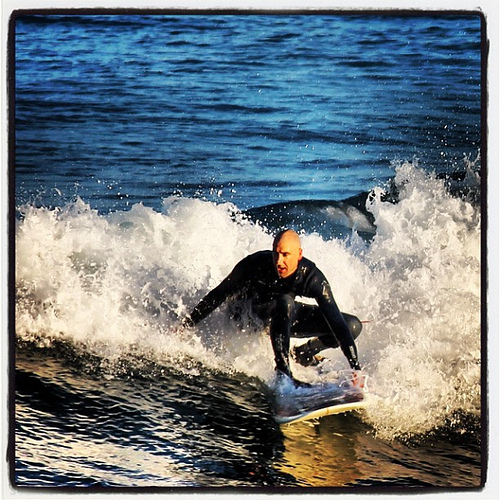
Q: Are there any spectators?
A: No, there are no spectators.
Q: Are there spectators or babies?
A: No, there are no spectators or babies.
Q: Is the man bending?
A: Yes, the man is bending.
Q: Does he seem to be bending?
A: Yes, the man is bending.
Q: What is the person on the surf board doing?
A: The man is bending.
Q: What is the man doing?
A: The man is bending.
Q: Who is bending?
A: The man is bending.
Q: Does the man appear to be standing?
A: No, the man is bending.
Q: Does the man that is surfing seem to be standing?
A: No, the man is bending.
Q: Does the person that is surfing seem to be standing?
A: No, the man is bending.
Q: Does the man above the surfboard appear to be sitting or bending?
A: The man is bending.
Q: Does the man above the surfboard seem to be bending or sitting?
A: The man is bending.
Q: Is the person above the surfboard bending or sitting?
A: The man is bending.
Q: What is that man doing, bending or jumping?
A: The man is bending.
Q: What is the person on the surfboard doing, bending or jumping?
A: The man is bending.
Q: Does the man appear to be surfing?
A: Yes, the man is surfing.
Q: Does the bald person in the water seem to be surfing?
A: Yes, the man is surfing.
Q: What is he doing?
A: The man is surfing.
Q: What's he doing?
A: The man is surfing.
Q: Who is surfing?
A: The man is surfing.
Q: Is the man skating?
A: No, the man is surfing.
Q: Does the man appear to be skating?
A: No, the man is surfing.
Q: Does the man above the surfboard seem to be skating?
A: No, the man is surfing.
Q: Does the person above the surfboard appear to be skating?
A: No, the man is surfing.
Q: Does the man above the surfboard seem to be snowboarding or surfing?
A: The man is surfing.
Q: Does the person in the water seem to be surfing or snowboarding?
A: The man is surfing.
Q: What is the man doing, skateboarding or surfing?
A: The man is surfing.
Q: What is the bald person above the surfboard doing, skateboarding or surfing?
A: The man is surfing.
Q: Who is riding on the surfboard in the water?
A: The man is riding on the surfboard.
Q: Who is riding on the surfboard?
A: The man is riding on the surfboard.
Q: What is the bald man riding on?
A: The man is riding on the surfboard.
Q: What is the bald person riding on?
A: The man is riding on the surfboard.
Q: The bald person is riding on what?
A: The man is riding on the surfboard.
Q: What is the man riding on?
A: The man is riding on the surfboard.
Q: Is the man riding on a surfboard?
A: Yes, the man is riding on a surfboard.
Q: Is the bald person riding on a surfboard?
A: Yes, the man is riding on a surfboard.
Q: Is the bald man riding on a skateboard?
A: No, the man is riding on a surfboard.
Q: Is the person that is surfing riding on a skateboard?
A: No, the man is riding on a surfboard.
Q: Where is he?
A: The man is in the water.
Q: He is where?
A: The man is in the water.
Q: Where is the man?
A: The man is in the water.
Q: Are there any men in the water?
A: Yes, there is a man in the water.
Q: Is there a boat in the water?
A: No, there is a man in the water.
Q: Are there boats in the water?
A: No, there is a man in the water.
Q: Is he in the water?
A: Yes, the man is in the water.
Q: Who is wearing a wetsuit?
A: The man is wearing a wetsuit.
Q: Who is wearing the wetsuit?
A: The man is wearing a wetsuit.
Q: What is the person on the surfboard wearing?
A: The man is wearing a wetsuit.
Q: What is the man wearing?
A: The man is wearing a wetsuit.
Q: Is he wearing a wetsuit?
A: Yes, the man is wearing a wetsuit.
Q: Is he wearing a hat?
A: No, the man is wearing a wetsuit.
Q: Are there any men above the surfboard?
A: Yes, there is a man above the surfboard.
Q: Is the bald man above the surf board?
A: Yes, the man is above the surf board.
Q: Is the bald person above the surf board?
A: Yes, the man is above the surf board.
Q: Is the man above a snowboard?
A: No, the man is above the surf board.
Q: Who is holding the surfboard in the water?
A: The man is holding the surfboard.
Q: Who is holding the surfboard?
A: The man is holding the surfboard.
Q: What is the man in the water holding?
A: The man is holding the surf board.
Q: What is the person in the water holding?
A: The man is holding the surf board.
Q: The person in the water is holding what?
A: The man is holding the surf board.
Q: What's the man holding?
A: The man is holding the surf board.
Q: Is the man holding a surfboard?
A: Yes, the man is holding a surfboard.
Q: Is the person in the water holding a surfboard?
A: Yes, the man is holding a surfboard.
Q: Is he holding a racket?
A: No, the man is holding a surfboard.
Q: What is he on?
A: The man is on the surfboard.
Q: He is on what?
A: The man is on the surfboard.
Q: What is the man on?
A: The man is on the surfboard.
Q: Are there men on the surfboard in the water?
A: Yes, there is a man on the surfboard.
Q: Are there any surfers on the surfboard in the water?
A: No, there is a man on the surfboard.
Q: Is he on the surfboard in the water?
A: Yes, the man is on the surfboard.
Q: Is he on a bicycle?
A: No, the man is on the surfboard.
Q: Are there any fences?
A: No, there are no fences.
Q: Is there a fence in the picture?
A: No, there are no fences.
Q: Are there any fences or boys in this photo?
A: No, there are no fences or boys.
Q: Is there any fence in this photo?
A: No, there are no fences.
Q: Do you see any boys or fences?
A: No, there are no fences or boys.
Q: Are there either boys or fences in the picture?
A: No, there are no fences or boys.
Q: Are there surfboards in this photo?
A: Yes, there is a surfboard.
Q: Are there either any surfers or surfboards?
A: Yes, there is a surfboard.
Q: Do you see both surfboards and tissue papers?
A: No, there is a surfboard but no tissues.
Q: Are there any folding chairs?
A: No, there are no folding chairs.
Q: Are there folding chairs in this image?
A: No, there are no folding chairs.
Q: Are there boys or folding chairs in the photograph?
A: No, there are no folding chairs or boys.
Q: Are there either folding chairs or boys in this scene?
A: No, there are no folding chairs or boys.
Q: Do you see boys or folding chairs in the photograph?
A: No, there are no folding chairs or boys.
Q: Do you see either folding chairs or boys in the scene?
A: No, there are no folding chairs or boys.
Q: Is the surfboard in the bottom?
A: Yes, the surfboard is in the bottom of the image.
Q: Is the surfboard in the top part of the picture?
A: No, the surfboard is in the bottom of the image.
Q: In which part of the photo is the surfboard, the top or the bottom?
A: The surfboard is in the bottom of the image.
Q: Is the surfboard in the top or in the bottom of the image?
A: The surfboard is in the bottom of the image.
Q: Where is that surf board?
A: The surf board is in the water.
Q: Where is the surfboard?
A: The surf board is in the water.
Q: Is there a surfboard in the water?
A: Yes, there is a surfboard in the water.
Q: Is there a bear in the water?
A: No, there is a surfboard in the water.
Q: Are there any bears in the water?
A: No, there is a surfboard in the water.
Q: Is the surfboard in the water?
A: Yes, the surfboard is in the water.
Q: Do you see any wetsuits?
A: Yes, there is a wetsuit.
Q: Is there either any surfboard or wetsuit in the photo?
A: Yes, there is a wetsuit.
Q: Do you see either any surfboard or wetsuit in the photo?
A: Yes, there is a wetsuit.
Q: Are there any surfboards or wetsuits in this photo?
A: Yes, there is a wetsuit.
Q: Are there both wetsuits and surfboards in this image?
A: Yes, there are both a wetsuit and a surfboard.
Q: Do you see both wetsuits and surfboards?
A: Yes, there are both a wetsuit and a surfboard.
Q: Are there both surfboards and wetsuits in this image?
A: Yes, there are both a wetsuit and a surfboard.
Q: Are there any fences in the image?
A: No, there are no fences.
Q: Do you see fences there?
A: No, there are no fences.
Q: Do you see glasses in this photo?
A: No, there are no glasses.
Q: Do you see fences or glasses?
A: No, there are no glasses or fences.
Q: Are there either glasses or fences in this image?
A: No, there are no glasses or fences.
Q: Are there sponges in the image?
A: No, there are no sponges.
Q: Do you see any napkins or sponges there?
A: No, there are no sponges or napkins.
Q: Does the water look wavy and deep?
A: Yes, the water is wavy and deep.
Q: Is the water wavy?
A: Yes, the water is wavy.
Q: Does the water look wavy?
A: Yes, the water is wavy.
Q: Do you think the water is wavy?
A: Yes, the water is wavy.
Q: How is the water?
A: The water is wavy.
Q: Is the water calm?
A: No, the water is wavy.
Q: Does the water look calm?
A: No, the water is wavy.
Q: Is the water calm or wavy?
A: The water is wavy.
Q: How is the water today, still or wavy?
A: The water is wavy.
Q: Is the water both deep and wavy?
A: Yes, the water is deep and wavy.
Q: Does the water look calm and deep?
A: No, the water is deep but wavy.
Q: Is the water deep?
A: Yes, the water is deep.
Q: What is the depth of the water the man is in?
A: The water is deep.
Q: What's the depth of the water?
A: The water is deep.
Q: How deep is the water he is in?
A: The water is deep.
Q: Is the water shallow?
A: No, the water is deep.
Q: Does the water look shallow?
A: No, the water is deep.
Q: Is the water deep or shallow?
A: The water is deep.